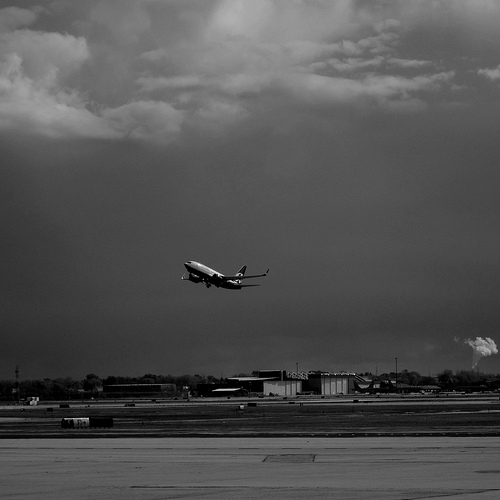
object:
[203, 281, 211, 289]
landing gear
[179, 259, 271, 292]
plane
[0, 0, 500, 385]
sky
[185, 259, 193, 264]
cockpit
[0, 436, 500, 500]
floor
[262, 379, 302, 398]
wall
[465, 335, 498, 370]
smoke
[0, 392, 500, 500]
ground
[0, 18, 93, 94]
cloud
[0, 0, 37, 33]
cloud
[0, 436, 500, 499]
runway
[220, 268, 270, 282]
wing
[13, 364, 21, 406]
tower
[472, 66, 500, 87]
clouds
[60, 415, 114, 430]
tank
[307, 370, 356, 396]
building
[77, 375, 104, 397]
trees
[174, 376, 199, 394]
trees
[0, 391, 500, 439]
field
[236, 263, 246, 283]
fin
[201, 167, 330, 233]
air